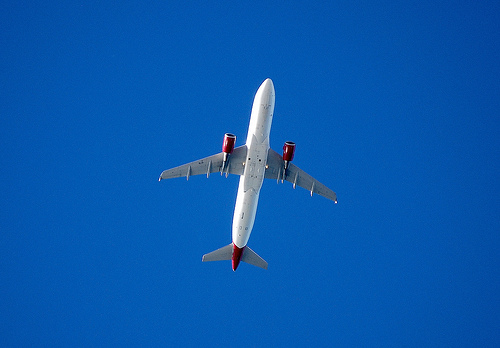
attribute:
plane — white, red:
[150, 49, 355, 280]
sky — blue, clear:
[0, 2, 497, 346]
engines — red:
[212, 127, 301, 163]